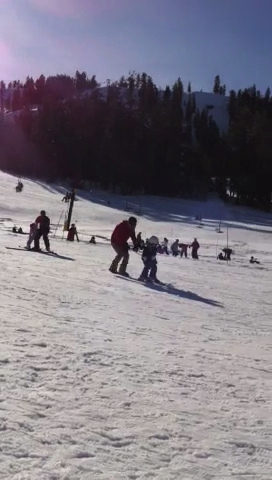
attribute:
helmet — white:
[145, 231, 164, 249]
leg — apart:
[41, 234, 50, 252]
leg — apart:
[32, 231, 40, 251]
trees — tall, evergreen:
[91, 96, 218, 170]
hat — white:
[146, 234, 159, 245]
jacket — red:
[110, 219, 135, 245]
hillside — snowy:
[0, 73, 268, 193]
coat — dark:
[141, 244, 157, 264]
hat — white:
[147, 235, 158, 244]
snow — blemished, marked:
[21, 341, 144, 395]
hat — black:
[124, 213, 144, 226]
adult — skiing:
[107, 213, 140, 276]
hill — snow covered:
[0, 165, 271, 479]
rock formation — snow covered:
[5, 83, 231, 184]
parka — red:
[108, 216, 134, 246]